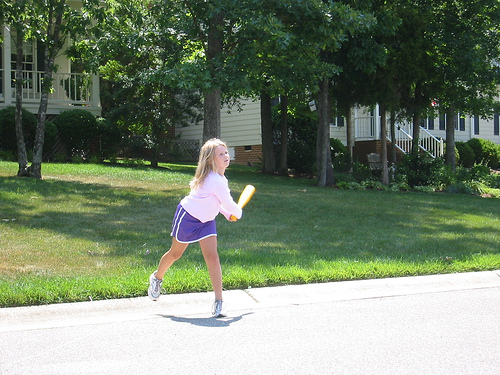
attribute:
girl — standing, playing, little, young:
[144, 137, 248, 318]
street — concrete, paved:
[1, 265, 500, 374]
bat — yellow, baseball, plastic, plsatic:
[230, 181, 258, 224]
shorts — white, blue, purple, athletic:
[169, 202, 221, 244]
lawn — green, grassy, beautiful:
[1, 157, 500, 311]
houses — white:
[1, 1, 108, 163]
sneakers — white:
[210, 296, 223, 318]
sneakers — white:
[146, 271, 165, 301]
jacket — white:
[184, 170, 242, 223]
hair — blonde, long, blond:
[188, 137, 231, 189]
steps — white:
[382, 112, 447, 184]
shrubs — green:
[52, 106, 103, 164]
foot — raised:
[147, 266, 163, 298]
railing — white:
[1, 66, 93, 104]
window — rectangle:
[243, 143, 253, 152]